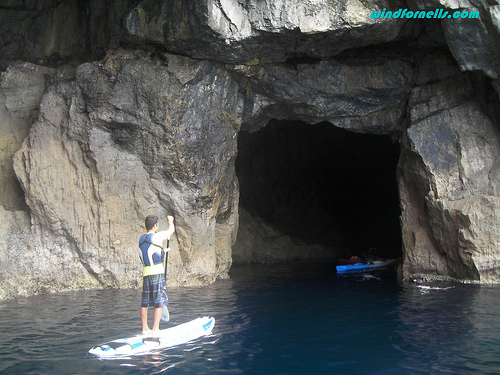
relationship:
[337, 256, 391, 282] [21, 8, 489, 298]
canoe in cave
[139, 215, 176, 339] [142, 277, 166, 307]
man wearing shorts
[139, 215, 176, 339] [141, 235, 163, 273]
man wearing shirt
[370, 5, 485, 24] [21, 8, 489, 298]
writing on top of cave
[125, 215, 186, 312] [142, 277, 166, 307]
man wearing blue shorts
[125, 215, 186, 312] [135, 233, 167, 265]
man wearing blue vest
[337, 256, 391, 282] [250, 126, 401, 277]
canoe in tunnel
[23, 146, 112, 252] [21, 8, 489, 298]
sunlight on cave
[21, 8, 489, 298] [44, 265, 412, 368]
cave reflected in water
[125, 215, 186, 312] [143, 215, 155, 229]
man has hair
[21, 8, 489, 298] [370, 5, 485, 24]
photo property of windfornells.com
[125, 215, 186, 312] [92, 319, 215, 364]
man on kayak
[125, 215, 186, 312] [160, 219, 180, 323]
man has paddler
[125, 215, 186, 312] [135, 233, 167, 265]
man wearing jacket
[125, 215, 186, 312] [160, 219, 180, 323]
man with paddler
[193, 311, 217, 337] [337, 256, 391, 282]
edge of canoe